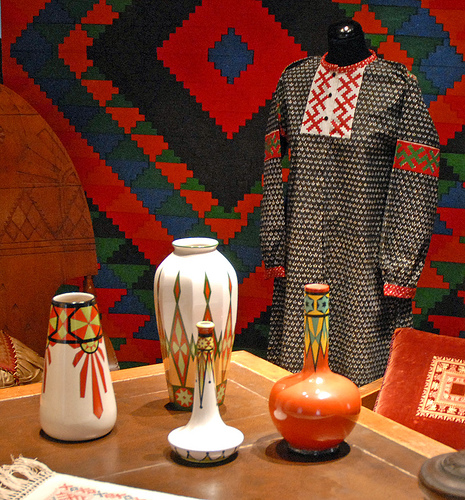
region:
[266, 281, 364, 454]
an orange American Indian vase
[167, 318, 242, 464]
an American Indian vase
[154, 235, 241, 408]
an American Indian vase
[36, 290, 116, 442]
an American Indian vase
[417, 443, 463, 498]
an artifact from early America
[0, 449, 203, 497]
a blanket created by an Indian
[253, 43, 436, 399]
an outfit created by early American Indians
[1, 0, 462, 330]
a large Indian blanket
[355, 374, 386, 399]
the wooden arm of a chair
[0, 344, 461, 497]
a table with blond wood trim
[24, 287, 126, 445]
small white vase sitting on table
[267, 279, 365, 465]
red glass bottle on table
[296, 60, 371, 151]
design on front of grey suit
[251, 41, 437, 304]
grey suit on mannequin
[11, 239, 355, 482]
bottles sitting on brown table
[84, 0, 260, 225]
design on wall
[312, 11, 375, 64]
black headless mannequin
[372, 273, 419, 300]
design on sleeve of suit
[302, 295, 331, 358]
yellow design on red bottle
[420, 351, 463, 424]
design on red pillow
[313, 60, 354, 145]
red and white symbols on a collar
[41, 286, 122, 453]
an angular vase with red green and white painting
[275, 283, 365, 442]
a rounded vase with an orange base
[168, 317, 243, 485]
a small oddly shaped white red and yellow vase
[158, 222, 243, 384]
a large white vase with red and green paint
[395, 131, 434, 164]
red and green armband on a blue and white dress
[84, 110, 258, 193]
a large ornate tapestry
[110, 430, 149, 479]
a brown table top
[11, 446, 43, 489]
white fringe at the end of a table cloth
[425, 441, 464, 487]
a bronze metal base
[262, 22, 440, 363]
a traditional costume on a dressform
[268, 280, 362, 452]
an orange vase with yellow, black and green designs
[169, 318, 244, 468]
a small white vase with designs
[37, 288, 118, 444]
a medium size vase with designs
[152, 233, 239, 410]
a larger vase with designs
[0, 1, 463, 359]
a woven rug with red, blue, black and green designs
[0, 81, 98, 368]
a curved brown item with drawn designs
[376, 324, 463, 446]
an orange pillow with white designs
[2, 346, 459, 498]
a wooden table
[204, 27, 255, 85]
a blue diamond design on a rug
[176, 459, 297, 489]
reflections on the brown table top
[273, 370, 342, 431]
small white spots on red vase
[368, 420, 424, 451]
yellow line at edge of table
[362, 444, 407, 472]
spotty pink lines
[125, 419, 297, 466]
small white base of vase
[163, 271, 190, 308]
green and orange design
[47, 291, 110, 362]
black lines on the vase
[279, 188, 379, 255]
coarse black and white cloth dress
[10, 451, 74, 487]
frills on white place mat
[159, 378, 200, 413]
small yellow and orange circle